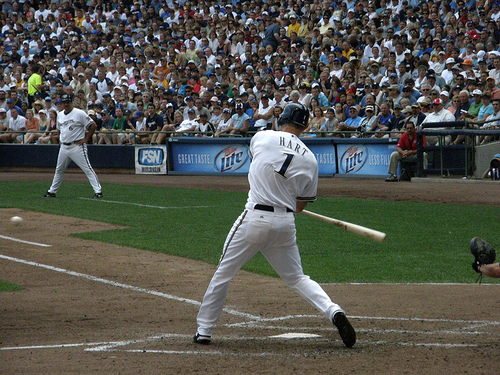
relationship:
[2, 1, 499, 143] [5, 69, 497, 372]
crowd at baseball game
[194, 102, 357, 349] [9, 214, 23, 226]
batter about to hit ball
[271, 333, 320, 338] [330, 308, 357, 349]
home plate beneath foot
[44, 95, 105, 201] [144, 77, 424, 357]
person observing action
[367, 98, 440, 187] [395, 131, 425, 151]
man in shirt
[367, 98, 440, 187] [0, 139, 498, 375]
man watching baseball game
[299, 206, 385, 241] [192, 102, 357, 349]
bat in hand of batter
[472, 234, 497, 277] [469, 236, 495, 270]
catcher wearing glove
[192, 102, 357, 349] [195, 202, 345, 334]
batter wearing pants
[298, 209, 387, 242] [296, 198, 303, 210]
bat in hand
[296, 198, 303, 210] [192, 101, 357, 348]
hand of person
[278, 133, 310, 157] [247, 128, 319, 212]
name on back of jersey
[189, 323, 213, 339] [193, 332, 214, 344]
cleat on cleat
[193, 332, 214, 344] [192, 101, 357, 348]
cleat of person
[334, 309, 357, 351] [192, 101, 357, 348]
cleat of person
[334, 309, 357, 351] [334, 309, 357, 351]
cleat on cleat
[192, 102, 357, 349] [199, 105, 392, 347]
batter swinging at a ball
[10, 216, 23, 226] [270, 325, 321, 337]
ball flying towards home plate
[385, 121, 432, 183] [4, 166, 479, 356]
man in playing field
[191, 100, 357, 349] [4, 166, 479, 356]
person in playing field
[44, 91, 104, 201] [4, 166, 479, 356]
person in playing field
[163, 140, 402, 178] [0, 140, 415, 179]
adertisment on wall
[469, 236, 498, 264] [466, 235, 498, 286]
catcher of catcher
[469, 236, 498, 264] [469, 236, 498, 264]
catcher wearing catcher